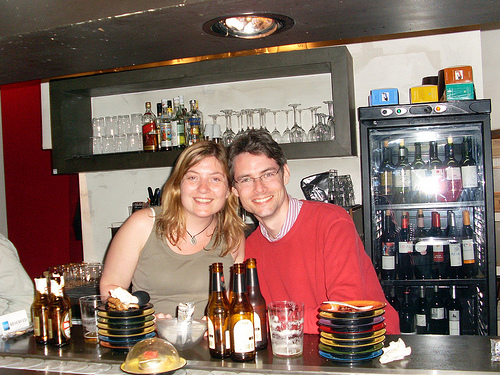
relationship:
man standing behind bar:
[225, 132, 400, 334] [2, 291, 498, 373]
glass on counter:
[266, 301, 302, 355] [2, 331, 498, 373]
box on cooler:
[367, 84, 401, 106] [357, 98, 497, 334]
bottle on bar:
[33, 270, 52, 347] [2, 291, 498, 373]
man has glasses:
[225, 132, 400, 334] [235, 163, 280, 188]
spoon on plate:
[322, 295, 380, 311] [316, 296, 386, 316]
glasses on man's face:
[232, 166, 283, 187] [227, 133, 290, 217]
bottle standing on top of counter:
[227, 262, 257, 362] [0, 316, 484, 367]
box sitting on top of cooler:
[408, 84, 439, 104] [356, 97, 485, 337]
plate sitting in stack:
[316, 296, 386, 316] [314, 300, 386, 364]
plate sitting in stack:
[317, 310, 385, 321] [314, 300, 386, 364]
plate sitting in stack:
[316, 318, 385, 329] [314, 300, 386, 364]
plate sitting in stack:
[316, 324, 386, 335] [314, 300, 386, 364]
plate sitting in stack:
[317, 337, 387, 350] [314, 300, 386, 364]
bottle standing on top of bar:
[51, 270, 73, 348] [2, 291, 498, 373]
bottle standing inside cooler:
[444, 211, 464, 275] [357, 98, 497, 334]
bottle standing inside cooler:
[381, 218, 393, 271] [356, 97, 485, 337]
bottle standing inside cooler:
[377, 212, 394, 272] [356, 97, 485, 337]